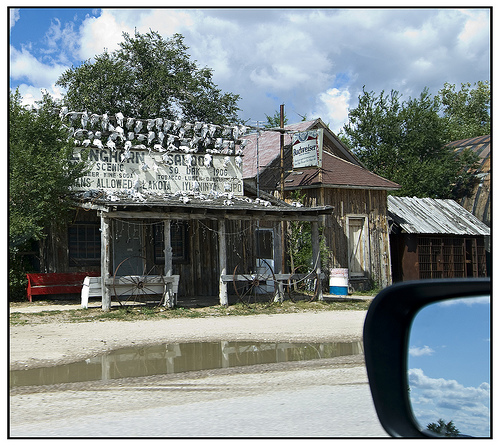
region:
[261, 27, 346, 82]
clouds above the land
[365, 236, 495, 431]
mirror in the photo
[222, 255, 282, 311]
wheel on the ground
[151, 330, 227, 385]
pond on the street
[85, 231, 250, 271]
pillars outside the building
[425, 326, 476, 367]
blue sky in the mirror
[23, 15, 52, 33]
blue sky behind clouds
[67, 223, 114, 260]
window on the building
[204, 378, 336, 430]
gray ground next to pond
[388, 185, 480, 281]
small brown structure next to building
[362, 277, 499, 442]
A car side mirror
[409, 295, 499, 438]
A mirror reflection of a clouded sky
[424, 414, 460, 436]
A mirror reflection of a tree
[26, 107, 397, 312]
An old building on a street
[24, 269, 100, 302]
The red bench next to the building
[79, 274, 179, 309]
The white bench on the building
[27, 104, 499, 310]
The wooden building on the road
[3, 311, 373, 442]
A tarmacked road opposite old buildings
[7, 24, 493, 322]
The overgrown trees within the buildings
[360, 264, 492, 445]
A dark car side mirror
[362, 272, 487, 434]
Rear view mirror of a vehicle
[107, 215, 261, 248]
Hanging string of white lights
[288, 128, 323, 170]
Budweiser can logo sign next to store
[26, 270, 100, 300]
Antique red wooden bench in front of store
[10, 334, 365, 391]
Water puddle in the road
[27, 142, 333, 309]
Old building with a Longhorn Saloon sign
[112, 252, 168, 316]
Vintage spoke metal wheel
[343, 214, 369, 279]
Doorway of an old wooden shack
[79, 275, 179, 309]
Antique white wooden bench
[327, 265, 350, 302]
Old metal barrel painted red, white, and blue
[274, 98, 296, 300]
a brown wooden post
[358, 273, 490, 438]
a side view mirror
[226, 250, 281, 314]
a brown wagon wheel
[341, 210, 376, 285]
a door on the building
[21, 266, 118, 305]
a red wooden bench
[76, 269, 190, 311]
a white wooden bench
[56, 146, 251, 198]
a sign on the store front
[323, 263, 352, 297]
a white and blue bucket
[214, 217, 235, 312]
a white wooden post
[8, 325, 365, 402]
a puddle of water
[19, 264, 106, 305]
THIS IS A BENCH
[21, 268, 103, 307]
THIS BENCH IS RED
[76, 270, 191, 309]
THIS BENCH IS WHITE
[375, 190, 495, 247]
THE ROOF IS TIN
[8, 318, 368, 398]
THE PUDDLE IS ON THE GROUND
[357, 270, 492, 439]
THE MIRROR IS ON THE RIGHT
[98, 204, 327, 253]
THE CHRISTMAS LIGHTS ARE ON THE BUILDING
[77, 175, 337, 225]
THE ROOF IS SAGGING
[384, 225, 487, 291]
THE BUILDING IS BROWN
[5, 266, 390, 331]
THE GRASS IS PATCHY AND GREEN